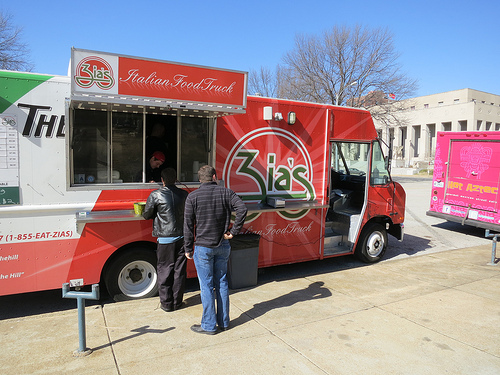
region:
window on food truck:
[74, 96, 110, 185]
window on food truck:
[112, 109, 144, 181]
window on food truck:
[145, 103, 180, 181]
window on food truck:
[180, 115, 210, 185]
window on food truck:
[368, 137, 369, 182]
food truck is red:
[2, 47, 407, 300]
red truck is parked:
[2, 46, 407, 298]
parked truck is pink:
[425, 130, 498, 235]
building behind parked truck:
[333, 88, 496, 178]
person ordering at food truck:
[145, 168, 189, 312]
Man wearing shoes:
[189, 317, 233, 334]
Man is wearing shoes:
[185, 317, 232, 336]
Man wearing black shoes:
[187, 313, 234, 336]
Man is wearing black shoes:
[186, 316, 231, 336]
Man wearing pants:
[190, 234, 234, 328]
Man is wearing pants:
[187, 230, 236, 332]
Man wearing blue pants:
[191, 233, 234, 331]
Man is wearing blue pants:
[188, 237, 233, 330]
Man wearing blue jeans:
[192, 240, 237, 330]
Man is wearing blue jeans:
[189, 237, 233, 329]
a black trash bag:
[224, 231, 264, 249]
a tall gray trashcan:
[230, 250, 260, 287]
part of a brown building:
[370, 88, 497, 178]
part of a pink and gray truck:
[424, 125, 497, 230]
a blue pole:
[61, 282, 103, 349]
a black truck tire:
[355, 220, 392, 263]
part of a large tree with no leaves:
[263, 21, 418, 111]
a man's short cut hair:
[195, 164, 218, 182]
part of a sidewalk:
[0, 240, 497, 373]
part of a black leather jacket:
[143, 187, 188, 237]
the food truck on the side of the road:
[1, 47, 405, 299]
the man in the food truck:
[145, 150, 164, 182]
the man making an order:
[143, 169, 189, 311]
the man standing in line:
[185, 163, 246, 334]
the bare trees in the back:
[0, 1, 416, 156]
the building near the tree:
[331, 88, 498, 175]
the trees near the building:
[247, 23, 418, 142]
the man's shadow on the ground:
[229, 280, 330, 327]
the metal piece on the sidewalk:
[60, 281, 99, 357]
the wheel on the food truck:
[360, 223, 387, 261]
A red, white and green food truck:
[1, 45, 408, 305]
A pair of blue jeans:
[189, 239, 235, 333]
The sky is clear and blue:
[1, 1, 499, 106]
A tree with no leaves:
[272, 22, 417, 133]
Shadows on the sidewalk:
[90, 279, 335, 354]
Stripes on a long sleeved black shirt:
[180, 180, 249, 254]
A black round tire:
[359, 222, 391, 264]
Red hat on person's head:
[144, 146, 168, 173]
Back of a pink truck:
[423, 126, 499, 235]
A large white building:
[333, 85, 498, 171]